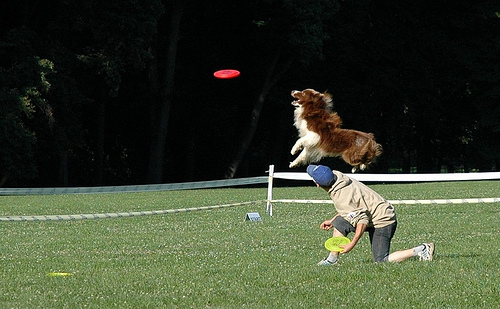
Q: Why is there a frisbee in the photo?
A: Frisbee game.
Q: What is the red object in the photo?
A: A frisbee.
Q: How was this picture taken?
A: Camera.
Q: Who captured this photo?
A: A photographer.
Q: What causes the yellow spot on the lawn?
A: Another frisbee.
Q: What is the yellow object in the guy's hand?
A: Frisbee.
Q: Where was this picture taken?
A: Dog park.